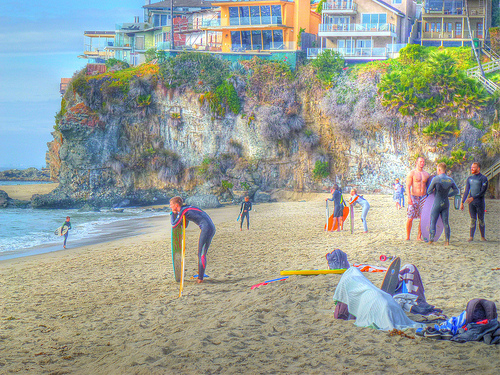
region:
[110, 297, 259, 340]
sand on the shore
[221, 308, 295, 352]
marks in the gray sand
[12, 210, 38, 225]
blue water in the ocean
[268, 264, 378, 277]
yellow board on the sand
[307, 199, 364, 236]
orange board in hand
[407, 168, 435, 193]
muscles on man's chest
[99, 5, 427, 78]
houses perched on rock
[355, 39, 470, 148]
yellow flowers growing on rocks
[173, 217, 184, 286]
surfboard is colorful and bright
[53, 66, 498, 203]
cliff is huge and rocky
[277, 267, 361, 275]
yellow surfboard is on the ground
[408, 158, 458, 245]
men are talking to each other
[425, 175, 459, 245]
man is wearing a wet suit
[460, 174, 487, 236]
man is wearing a wet suit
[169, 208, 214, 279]
man is wearing a wet suit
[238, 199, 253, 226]
man is wearing a wet suit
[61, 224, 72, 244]
man is wearing a wet suit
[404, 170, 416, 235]
the man is built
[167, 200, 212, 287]
man is leaning on board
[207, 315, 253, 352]
sand is brown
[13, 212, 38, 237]
the water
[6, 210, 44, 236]
the ocean water is blue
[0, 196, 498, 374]
man with surfboard standing on the sand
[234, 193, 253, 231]
man is wearing a wetsuit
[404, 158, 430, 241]
man is wearing multi colored swim trunks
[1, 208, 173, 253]
man walking out of the water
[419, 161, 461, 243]
man holding purple boogie board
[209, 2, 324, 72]
windows on yellow house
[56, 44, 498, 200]
stairs leading up the cliff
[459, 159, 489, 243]
man is wearing a wetsuit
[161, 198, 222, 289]
A man is standing next to his surfboard.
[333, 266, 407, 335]
A person is laying on the beach covered in a towel.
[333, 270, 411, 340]
The towel is white.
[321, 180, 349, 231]
A person is standing next to a red surfboard.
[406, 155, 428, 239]
A tall shirtless man is speaking to another man.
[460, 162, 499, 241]
A man is standing wearing a black wet suit.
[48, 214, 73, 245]
A man is just coming out of the water.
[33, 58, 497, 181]
A rocky cliff is by the water on the beach.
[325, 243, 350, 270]
A bag is left on the sandy beach.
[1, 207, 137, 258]
You can see the water in the distance.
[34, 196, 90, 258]
a surfer is getting out the sea